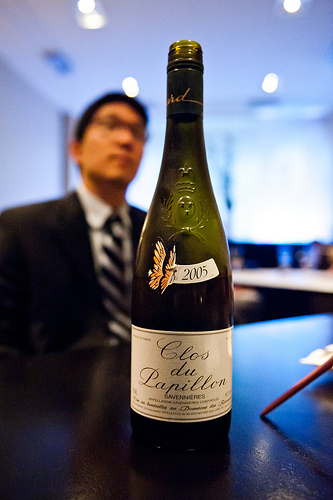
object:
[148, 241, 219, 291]
label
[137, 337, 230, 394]
black letter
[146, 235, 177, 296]
butterfly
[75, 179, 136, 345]
shirt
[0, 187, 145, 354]
jacket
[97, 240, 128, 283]
stripe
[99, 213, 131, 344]
tie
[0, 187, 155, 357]
suit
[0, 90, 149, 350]
person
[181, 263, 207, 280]
year 2005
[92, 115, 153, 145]
glasses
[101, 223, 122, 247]
stripe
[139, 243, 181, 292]
an insect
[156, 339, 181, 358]
letter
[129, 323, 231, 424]
label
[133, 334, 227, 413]
lettering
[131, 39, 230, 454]
bottle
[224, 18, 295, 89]
ceiling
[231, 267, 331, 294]
table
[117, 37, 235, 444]
wine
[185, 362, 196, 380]
letter bottle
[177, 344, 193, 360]
black letter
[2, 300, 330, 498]
table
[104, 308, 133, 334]
stripe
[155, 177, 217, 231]
imprint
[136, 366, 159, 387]
letter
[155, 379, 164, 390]
letter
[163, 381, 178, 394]
letter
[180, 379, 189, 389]
letter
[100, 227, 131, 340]
stripe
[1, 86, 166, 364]
man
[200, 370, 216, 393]
letter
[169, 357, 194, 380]
letter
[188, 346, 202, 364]
letter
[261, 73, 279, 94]
lights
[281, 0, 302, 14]
lights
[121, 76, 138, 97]
lights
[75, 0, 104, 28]
lights